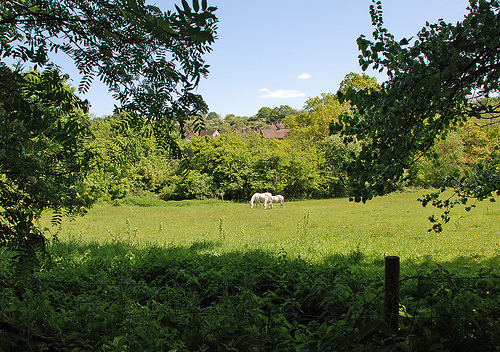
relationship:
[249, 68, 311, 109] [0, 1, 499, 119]
clouds in sky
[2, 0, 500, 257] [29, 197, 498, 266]
trees behind grass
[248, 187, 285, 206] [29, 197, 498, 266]
horses in grass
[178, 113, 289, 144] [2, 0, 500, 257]
roofs in trees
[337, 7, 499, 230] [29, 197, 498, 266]
branches hanging over grass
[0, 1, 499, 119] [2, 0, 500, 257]
sky above trees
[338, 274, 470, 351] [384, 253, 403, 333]
wire beside fencepost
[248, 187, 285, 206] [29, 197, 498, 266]
horses eating grass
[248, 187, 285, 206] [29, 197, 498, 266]
horses on grass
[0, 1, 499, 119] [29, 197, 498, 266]
sky above grass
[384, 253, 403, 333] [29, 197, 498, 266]
fencepost in grass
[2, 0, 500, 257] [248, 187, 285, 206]
trees behind horses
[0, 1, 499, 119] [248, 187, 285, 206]
sky above horses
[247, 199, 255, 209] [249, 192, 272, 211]
head of a horse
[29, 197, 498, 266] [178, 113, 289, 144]
grass in front of roofs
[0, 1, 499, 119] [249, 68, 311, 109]
sky has clouds